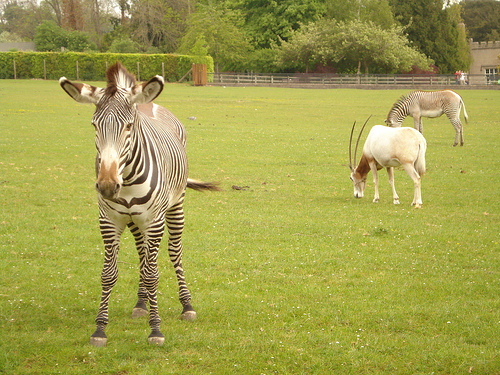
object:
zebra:
[54, 61, 225, 351]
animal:
[345, 113, 429, 211]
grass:
[0, 81, 499, 374]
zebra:
[381, 87, 471, 149]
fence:
[201, 72, 499, 88]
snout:
[94, 174, 120, 197]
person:
[453, 69, 462, 84]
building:
[466, 28, 499, 90]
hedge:
[0, 49, 215, 85]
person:
[462, 70, 471, 84]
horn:
[349, 116, 356, 174]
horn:
[354, 112, 375, 172]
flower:
[326, 339, 334, 347]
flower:
[270, 355, 276, 362]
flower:
[236, 324, 242, 332]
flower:
[197, 355, 203, 364]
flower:
[446, 318, 452, 326]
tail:
[185, 171, 241, 194]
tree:
[173, 0, 252, 73]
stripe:
[137, 124, 160, 204]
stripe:
[123, 122, 151, 185]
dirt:
[147, 334, 168, 346]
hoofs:
[146, 329, 168, 348]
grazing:
[353, 193, 366, 201]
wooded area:
[1, 0, 499, 374]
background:
[0, 0, 499, 85]